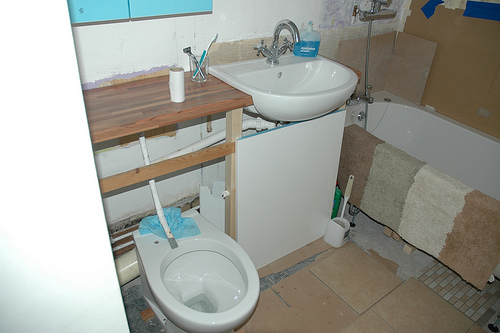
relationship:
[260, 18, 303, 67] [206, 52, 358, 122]
faucet on sink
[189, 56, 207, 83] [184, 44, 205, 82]
cup holding razor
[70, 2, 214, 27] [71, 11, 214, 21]
mirror has bottom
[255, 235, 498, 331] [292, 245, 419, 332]
floor has tiles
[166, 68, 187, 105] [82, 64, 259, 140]
paper on stand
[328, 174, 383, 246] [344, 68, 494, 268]
brush near tub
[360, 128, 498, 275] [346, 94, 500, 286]
rug on bathtub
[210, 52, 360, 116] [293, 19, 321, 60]
sink with soap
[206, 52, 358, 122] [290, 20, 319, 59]
sink with soap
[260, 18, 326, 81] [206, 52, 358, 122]
faucet on sink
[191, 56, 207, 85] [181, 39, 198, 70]
cup with razor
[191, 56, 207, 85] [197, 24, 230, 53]
cup with tooth brush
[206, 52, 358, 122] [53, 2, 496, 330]
sink in bathroom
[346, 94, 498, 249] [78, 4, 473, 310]
bathtub in bathroom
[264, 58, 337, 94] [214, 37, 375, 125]
circle of sink